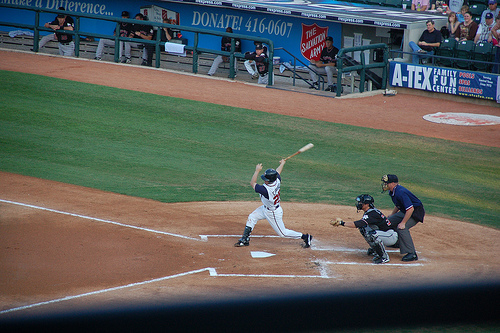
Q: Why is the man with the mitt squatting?
A: Catch the ball.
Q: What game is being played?
A: Baseball.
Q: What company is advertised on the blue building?
A: The Salvation army.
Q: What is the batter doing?
A: Swinging the bat.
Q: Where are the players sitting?
A: In the dugout.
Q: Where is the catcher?
A: Behind the batter.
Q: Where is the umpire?
A: Behind the catcher.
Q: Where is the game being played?
A: Baseball field.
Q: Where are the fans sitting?
A: In the stands.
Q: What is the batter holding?
A: Baseball bat.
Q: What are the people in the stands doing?
A: Watching the game.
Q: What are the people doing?
A: Playing baseball.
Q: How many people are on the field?
A: Three.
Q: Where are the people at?
A: Baseball field.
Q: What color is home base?
A: White.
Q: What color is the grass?
A: Green.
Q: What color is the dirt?
A: Brown.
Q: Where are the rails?
A: The Dugout.